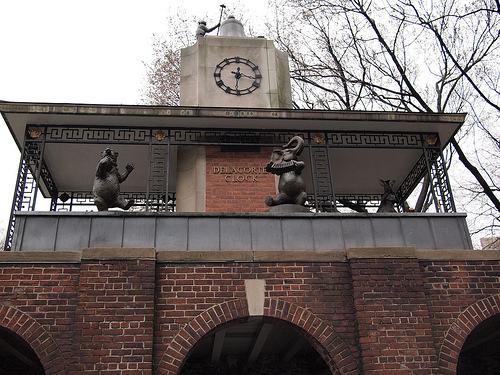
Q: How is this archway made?
A: With bricks.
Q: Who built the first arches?
A: The Romans.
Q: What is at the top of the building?
A: A clock.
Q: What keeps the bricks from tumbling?
A: Support columns.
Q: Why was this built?
A: As a tower.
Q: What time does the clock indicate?
A: 3:30.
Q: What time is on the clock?
A: 3:31.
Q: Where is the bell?
A: Above the clock.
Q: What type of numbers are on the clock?
A: Roman numerals.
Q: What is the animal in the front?
A: Elephant.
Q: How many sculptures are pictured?
A: 3.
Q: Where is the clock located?
A: On building.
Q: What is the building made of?
A: Brick.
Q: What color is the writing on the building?
A: Gold.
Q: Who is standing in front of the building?
A: Nobody.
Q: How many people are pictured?
A: 0.